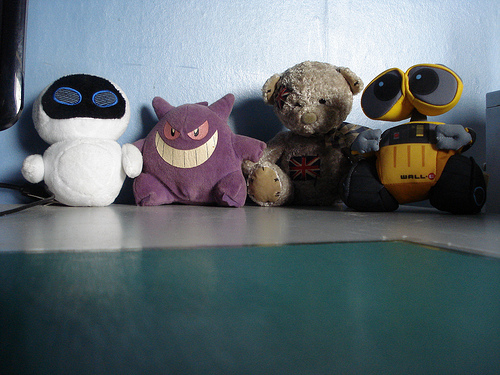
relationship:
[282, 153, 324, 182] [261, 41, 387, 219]
flag sewn on bear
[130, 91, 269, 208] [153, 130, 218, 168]
toy with teeth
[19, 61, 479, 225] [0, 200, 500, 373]
toys on table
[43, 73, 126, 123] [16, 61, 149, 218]
face on animal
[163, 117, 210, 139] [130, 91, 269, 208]
eyes of toy